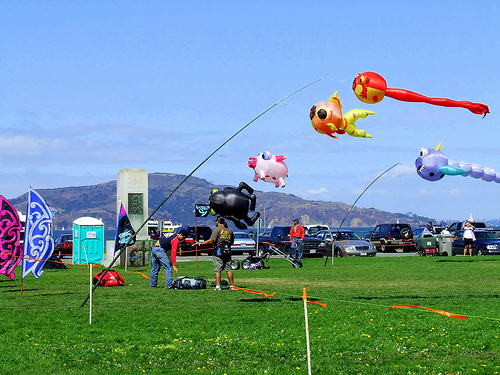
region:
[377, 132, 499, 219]
The kite is airborne.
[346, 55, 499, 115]
The kite is airborne.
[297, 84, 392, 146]
The kite is airborne.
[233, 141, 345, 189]
The kite is airborne.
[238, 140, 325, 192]
The kite is colorful.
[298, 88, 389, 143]
The kite is colorful.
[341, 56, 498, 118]
The kite is colorful.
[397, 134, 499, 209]
The kite is colorful.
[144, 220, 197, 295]
The man is bent over.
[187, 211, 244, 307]
The man is standing on the grass.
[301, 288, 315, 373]
gray post supporting a rope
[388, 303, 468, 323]
orange streamers tied to the rope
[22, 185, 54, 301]
a fancy blue banner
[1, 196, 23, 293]
fancy black and purple banner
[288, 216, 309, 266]
person wearing a red jacket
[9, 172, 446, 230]
tall mountain under the sky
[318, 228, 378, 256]
silver car is parked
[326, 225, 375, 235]
water in front of the mountain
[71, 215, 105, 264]
bright blue port a potty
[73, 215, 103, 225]
white a roof on top of the port a potty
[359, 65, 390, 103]
red and yellow kite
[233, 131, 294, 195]
white and red kite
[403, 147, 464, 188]
blue kite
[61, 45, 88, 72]
white clouds in blue sky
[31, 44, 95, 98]
white clouds in blue sky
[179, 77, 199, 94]
white clouds in blue sky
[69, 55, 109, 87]
white clouds in blue sky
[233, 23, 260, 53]
white clouds in blue sky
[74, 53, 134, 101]
white clouds in blue sky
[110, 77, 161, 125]
white clouds in blue sky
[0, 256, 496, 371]
white rope with orange flags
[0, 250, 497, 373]
grassy field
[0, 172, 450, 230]
hill in the background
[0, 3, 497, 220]
blue sky with white clouds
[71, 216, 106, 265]
portable toilet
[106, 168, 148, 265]
white concrete structure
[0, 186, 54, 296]
pink and blue flags on stakes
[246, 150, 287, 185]
pig kite with wings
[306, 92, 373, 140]
orange and yellow fish kite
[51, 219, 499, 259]
cars parked beside field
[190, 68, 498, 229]
Character balloons floating in the air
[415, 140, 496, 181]
Purple and aqua colored character balloon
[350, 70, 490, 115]
character balloon in yellow and red color floating in the air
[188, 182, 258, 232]
Black character balloon being lifted into the air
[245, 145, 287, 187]
light pink and dark pink character balloon flying through the air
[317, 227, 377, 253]
Silver colored car parked on the side of the road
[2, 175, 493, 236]
Tall mountains in the distance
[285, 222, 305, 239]
Red shirt the person is wearing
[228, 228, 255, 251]
The back of a light colored car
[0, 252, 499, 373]
Green grass people are walking on